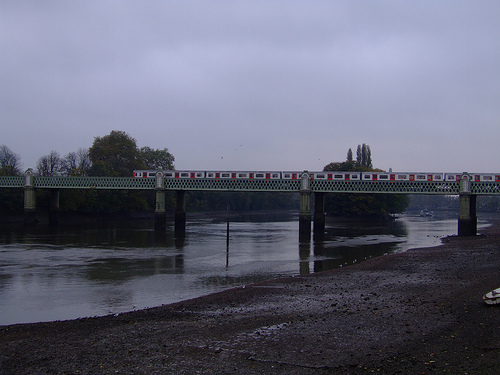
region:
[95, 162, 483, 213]
train on bridge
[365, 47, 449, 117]
white clouds in blue sky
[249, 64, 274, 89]
white clouds in blue sky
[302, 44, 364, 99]
white clouds in blue sky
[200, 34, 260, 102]
white clouds in blue sky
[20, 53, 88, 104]
white clouds in blue sky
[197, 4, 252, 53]
white clouds in blue sky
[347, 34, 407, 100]
white clouds in blue sky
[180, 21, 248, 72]
white clouds in blue sky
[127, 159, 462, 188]
train on bridge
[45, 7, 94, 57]
white clouds in blue sky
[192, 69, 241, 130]
white clouds in blue sky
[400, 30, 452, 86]
white clouds in blue sky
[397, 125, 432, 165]
white clouds in blue sky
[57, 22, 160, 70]
white clouds in blue sky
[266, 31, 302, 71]
white clouds in blue sky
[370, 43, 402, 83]
white clouds in blue sky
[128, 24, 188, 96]
white clouds in blue sky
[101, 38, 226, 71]
white clouds in blue sky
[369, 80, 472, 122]
white clouds in blue sky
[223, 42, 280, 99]
white clouds in blue sky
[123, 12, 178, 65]
white clouds in blue sky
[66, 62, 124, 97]
white clouds in blue sky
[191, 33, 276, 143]
white clouds in blue sky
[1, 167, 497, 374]
bridge over a body of water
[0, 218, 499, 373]
wet sand or dirt next to a body of water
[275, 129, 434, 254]
an island of trees in the middle of a body of water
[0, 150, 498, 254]
train going over a bridge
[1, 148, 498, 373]
train traveling over a body of water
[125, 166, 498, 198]
red train with white trim around the windows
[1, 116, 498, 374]
lots of trees on the opposite bank of a body of water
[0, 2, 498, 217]
grey overcast skies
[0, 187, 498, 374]
ripples in a body of water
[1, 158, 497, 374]
reflection of a bridge in a body of water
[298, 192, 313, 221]
pillar under a bridge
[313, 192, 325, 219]
pillar under a bridge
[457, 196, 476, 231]
pillar under a bridge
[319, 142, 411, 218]
a tree next to water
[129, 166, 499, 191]
a train on a bridge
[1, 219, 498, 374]
a sandy shore line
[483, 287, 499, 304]
tip of a water vessel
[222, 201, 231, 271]
reflection in water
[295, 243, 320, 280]
reflection of columns in water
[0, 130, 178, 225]
trees behind a bridge